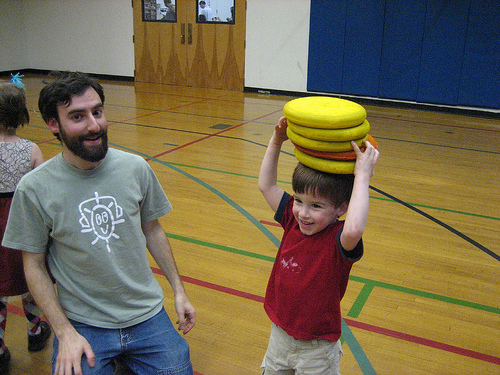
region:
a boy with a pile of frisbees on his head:
[229, 56, 401, 373]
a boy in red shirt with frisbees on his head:
[230, 89, 376, 371]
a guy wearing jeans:
[13, 70, 192, 371]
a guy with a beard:
[28, 72, 118, 182]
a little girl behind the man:
[1, 67, 43, 373]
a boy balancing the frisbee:
[241, 92, 383, 264]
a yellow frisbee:
[276, 90, 369, 130]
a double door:
[125, 0, 273, 97]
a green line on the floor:
[392, 270, 449, 311]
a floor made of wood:
[424, 155, 471, 204]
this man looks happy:
[7, 53, 209, 353]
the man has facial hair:
[12, 70, 144, 175]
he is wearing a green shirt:
[36, 77, 205, 369]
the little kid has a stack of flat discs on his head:
[259, 84, 398, 372]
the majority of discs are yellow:
[283, 100, 393, 200]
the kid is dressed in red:
[235, 117, 383, 369]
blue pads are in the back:
[318, 3, 488, 110]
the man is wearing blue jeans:
[27, 299, 232, 371]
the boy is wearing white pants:
[249, 330, 356, 373]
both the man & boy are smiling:
[16, 37, 431, 282]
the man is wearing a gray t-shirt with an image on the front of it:
[36, 162, 191, 313]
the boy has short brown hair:
[286, 162, 335, 204]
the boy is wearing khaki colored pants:
[266, 332, 346, 373]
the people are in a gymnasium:
[172, 85, 259, 295]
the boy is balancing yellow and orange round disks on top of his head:
[286, 91, 366, 177]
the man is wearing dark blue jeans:
[108, 319, 199, 366]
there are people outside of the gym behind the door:
[146, 0, 255, 53]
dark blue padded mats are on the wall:
[307, 9, 494, 99]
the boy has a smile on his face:
[295, 188, 325, 235]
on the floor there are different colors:
[185, 114, 260, 342]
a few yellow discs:
[280, 88, 392, 181]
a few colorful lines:
[148, 83, 487, 367]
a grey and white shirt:
[2, 146, 189, 331]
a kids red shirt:
[249, 188, 364, 358]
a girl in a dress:
[0, 79, 59, 368]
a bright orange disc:
[291, 134, 386, 165]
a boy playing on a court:
[245, 80, 429, 373]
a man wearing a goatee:
[34, 60, 128, 180]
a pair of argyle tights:
[0, 277, 52, 360]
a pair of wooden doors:
[122, 2, 262, 107]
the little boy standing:
[250, 90, 380, 373]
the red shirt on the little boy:
[261, 190, 352, 337]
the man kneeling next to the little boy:
[12, 72, 204, 374]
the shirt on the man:
[11, 150, 173, 320]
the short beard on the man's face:
[56, 121, 113, 163]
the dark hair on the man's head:
[34, 72, 99, 103]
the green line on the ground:
[363, 264, 499, 325]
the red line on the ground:
[370, 317, 498, 357]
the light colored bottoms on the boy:
[256, 320, 346, 374]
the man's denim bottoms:
[52, 300, 194, 374]